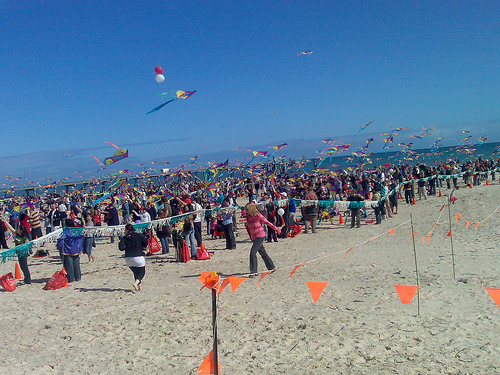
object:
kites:
[0, 122, 495, 174]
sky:
[3, 1, 495, 142]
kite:
[145, 90, 197, 116]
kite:
[92, 141, 128, 167]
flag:
[192, 209, 500, 375]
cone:
[410, 182, 491, 203]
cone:
[12, 262, 23, 280]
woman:
[118, 224, 149, 292]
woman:
[244, 203, 281, 276]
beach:
[3, 178, 494, 373]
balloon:
[155, 73, 164, 83]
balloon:
[154, 66, 163, 75]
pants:
[129, 266, 145, 285]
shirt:
[246, 211, 281, 240]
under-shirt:
[125, 256, 146, 268]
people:
[0, 156, 499, 249]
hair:
[244, 202, 259, 218]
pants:
[250, 236, 275, 274]